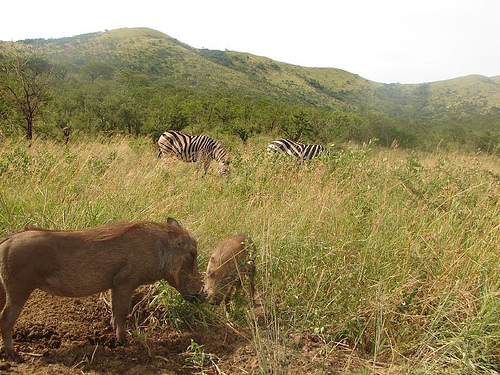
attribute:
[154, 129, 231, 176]
zebras — standing, hidden, grazing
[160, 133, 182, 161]
stripes — black, white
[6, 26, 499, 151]
hill — green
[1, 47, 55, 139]
trees — green, small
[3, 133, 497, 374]
grass — tall, grassy, green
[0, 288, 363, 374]
dirt — brown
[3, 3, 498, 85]
sky — bright, clear, gray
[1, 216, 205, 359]
animals — brown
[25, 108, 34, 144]
trunk — brown